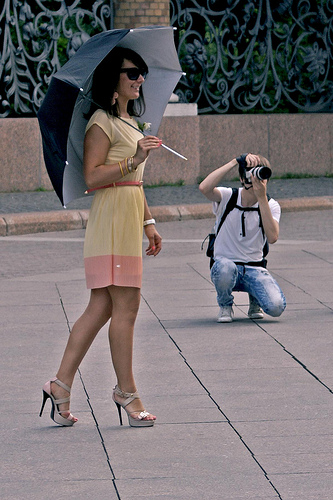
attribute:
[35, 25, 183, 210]
umbrella — black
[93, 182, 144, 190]
belt — pink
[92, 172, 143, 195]
waist — woman's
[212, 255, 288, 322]
jeans — faded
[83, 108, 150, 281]
dress. — yellow, pink 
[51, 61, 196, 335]
dress — yellow, pink, short, sleeved 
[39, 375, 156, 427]
shoes — high heeled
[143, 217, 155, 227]
band — white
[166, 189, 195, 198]
stones — gray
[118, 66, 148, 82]
sunglasses — black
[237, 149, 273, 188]
camera — black, white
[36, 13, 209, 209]
umbrella — Black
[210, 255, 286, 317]
jeans — blue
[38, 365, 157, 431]
sandals — woman's, strappy